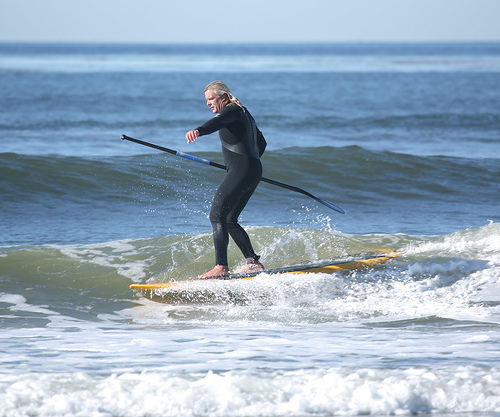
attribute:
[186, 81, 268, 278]
man — surfing, surfing the waves, elder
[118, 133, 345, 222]
paddle — black, blue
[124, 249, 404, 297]
surfboard — yellow, black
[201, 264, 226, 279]
foot — bare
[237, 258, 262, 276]
foot — bare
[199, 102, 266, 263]
wetsuit — black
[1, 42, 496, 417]
ocean — large, blue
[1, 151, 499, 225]
wave — coastal, coming in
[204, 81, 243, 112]
hair — wet, blond, long, black, blonde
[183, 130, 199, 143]
hand — bare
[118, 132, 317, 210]
pole — black, long, blue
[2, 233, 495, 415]
foamy area — white